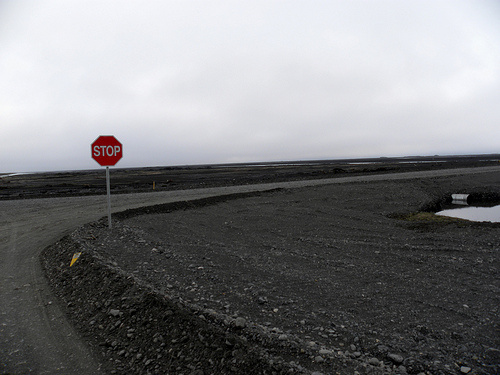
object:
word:
[90, 140, 120, 158]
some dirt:
[189, 220, 335, 300]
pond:
[434, 189, 500, 224]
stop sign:
[90, 133, 126, 231]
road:
[0, 164, 500, 374]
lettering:
[92, 143, 98, 157]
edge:
[89, 141, 98, 163]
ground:
[0, 166, 500, 373]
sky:
[1, 2, 500, 171]